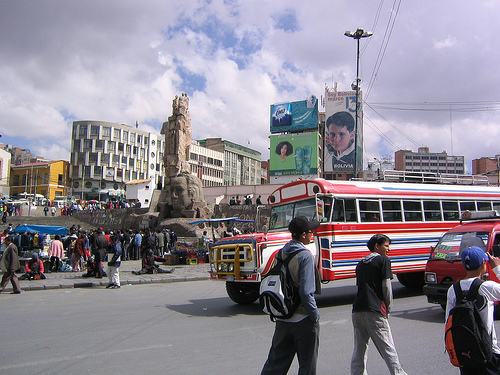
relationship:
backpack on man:
[258, 248, 305, 321] [260, 216, 322, 374]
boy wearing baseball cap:
[446, 246, 499, 374] [461, 246, 490, 268]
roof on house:
[10, 159, 71, 169] [11, 159, 69, 201]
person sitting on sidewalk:
[132, 249, 174, 275] [0, 258, 216, 292]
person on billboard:
[325, 111, 362, 170] [323, 90, 363, 173]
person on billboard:
[274, 141, 293, 161] [270, 132, 318, 176]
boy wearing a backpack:
[446, 246, 499, 374] [443, 278, 491, 368]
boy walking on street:
[446, 246, 499, 374] [1, 279, 499, 374]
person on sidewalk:
[132, 249, 174, 275] [0, 258, 216, 292]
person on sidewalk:
[18, 253, 46, 280] [0, 258, 216, 292]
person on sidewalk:
[92, 228, 106, 278] [0, 258, 216, 292]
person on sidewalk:
[48, 234, 65, 272] [0, 258, 216, 292]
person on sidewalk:
[134, 229, 142, 260] [0, 258, 216, 292]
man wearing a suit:
[1, 235, 21, 294] [1, 244, 21, 293]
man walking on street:
[1, 235, 21, 294] [1, 279, 499, 374]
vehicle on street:
[422, 218, 500, 310] [1, 279, 499, 374]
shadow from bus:
[165, 281, 426, 317] [209, 178, 499, 301]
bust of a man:
[157, 173, 226, 244] [159, 173, 222, 244]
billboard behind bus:
[268, 95, 319, 134] [209, 178, 499, 301]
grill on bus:
[208, 243, 254, 282] [209, 178, 499, 301]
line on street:
[1, 306, 442, 369] [1, 279, 499, 374]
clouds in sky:
[1, 1, 500, 175] [1, 1, 500, 174]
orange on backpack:
[443, 314, 471, 367] [443, 278, 491, 368]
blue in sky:
[1, 0, 499, 174] [1, 1, 500, 174]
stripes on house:
[9, 160, 70, 203] [11, 159, 69, 201]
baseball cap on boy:
[461, 246, 490, 268] [446, 246, 499, 374]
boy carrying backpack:
[446, 246, 499, 374] [443, 278, 491, 368]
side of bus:
[257, 181, 499, 284] [209, 178, 499, 301]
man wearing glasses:
[260, 216, 322, 374] [305, 228, 314, 234]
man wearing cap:
[260, 216, 322, 374] [288, 216, 319, 234]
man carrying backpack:
[260, 216, 322, 374] [258, 248, 305, 321]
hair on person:
[275, 141, 293, 155] [274, 141, 293, 161]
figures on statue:
[174, 93, 189, 115] [158, 92, 194, 207]